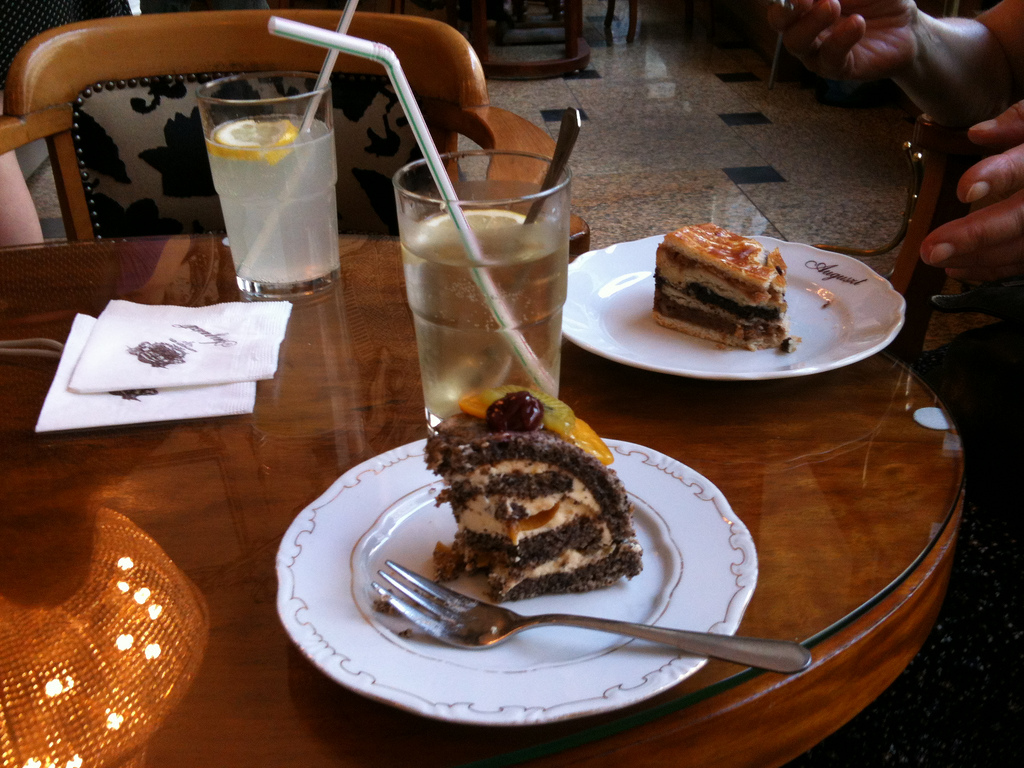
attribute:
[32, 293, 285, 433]
napkins — white, paper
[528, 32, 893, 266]
floor — shining, linoleum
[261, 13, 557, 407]
straw — large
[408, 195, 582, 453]
glass — clear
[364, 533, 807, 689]
fork — small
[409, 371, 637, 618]
cake — sliced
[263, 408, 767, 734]
plate — small, glass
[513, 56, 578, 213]
straw — black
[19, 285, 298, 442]
napkins — small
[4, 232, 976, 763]
wood table — glass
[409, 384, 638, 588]
dessert — layered, chocolate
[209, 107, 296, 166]
lemon slice — floating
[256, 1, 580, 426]
straw — flexi